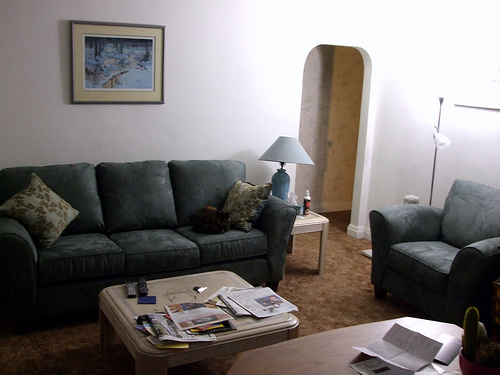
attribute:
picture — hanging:
[55, 10, 190, 120]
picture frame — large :
[66, 16, 166, 107]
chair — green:
[364, 179, 499, 330]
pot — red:
[456, 351, 483, 371]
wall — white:
[167, 27, 318, 211]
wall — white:
[5, 0, 430, 262]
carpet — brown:
[291, 243, 360, 303]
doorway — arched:
[283, 29, 383, 249]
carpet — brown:
[282, 232, 372, 328]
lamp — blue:
[266, 135, 312, 192]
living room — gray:
[3, 6, 488, 368]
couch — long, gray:
[6, 163, 293, 308]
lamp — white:
[424, 121, 454, 150]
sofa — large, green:
[10, 136, 311, 336]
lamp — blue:
[257, 135, 313, 199]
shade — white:
[258, 136, 313, 164]